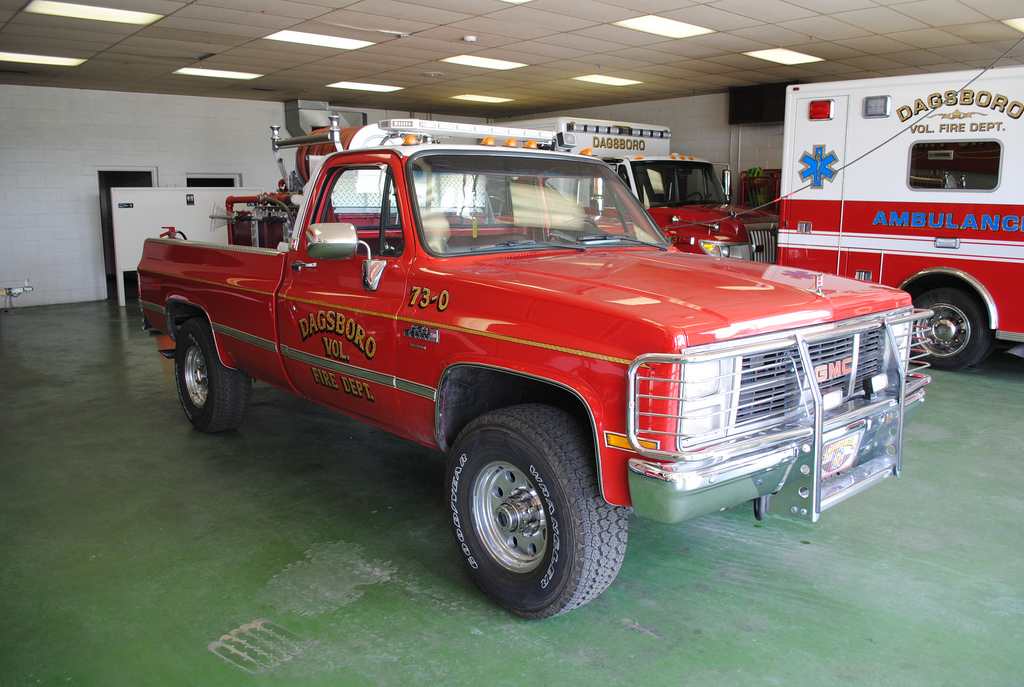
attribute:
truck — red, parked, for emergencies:
[135, 142, 934, 622]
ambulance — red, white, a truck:
[773, 60, 1022, 365]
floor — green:
[5, 299, 1022, 681]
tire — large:
[444, 400, 624, 621]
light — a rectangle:
[442, 52, 524, 74]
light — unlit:
[803, 98, 835, 119]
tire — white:
[171, 314, 247, 435]